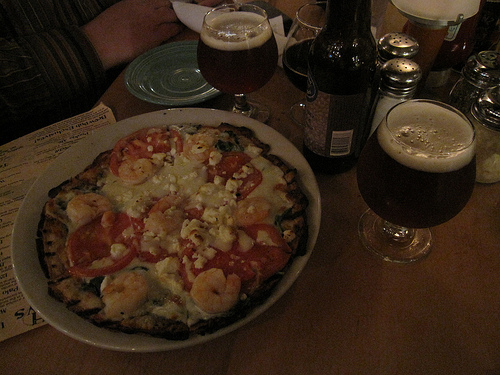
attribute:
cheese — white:
[103, 149, 246, 266]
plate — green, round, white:
[11, 110, 313, 350]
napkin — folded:
[159, 0, 296, 70]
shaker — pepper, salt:
[364, 29, 427, 140]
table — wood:
[367, 225, 493, 287]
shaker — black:
[441, 47, 499, 112]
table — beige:
[307, 269, 497, 371]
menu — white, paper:
[1, 101, 132, 343]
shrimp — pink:
[201, 268, 240, 300]